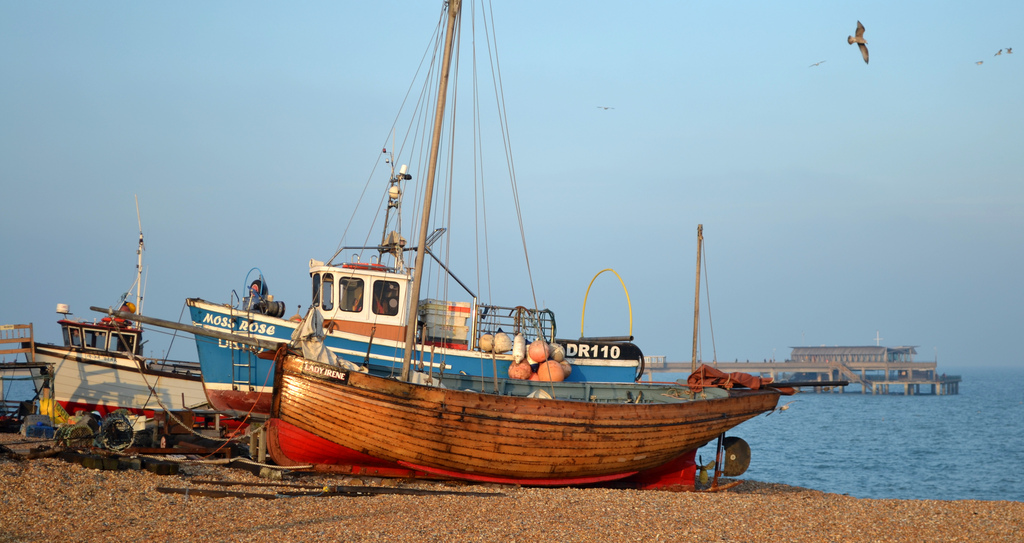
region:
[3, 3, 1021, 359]
blue of daytime sky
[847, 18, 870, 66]
extended wings of flying bird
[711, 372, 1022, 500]
surface of choppy water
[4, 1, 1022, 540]
boats on shore near water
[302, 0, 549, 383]
boat mast with no sail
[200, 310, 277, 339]
white words on blue background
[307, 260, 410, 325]
wheel house of boat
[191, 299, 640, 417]
blue body of boat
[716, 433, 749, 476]
rutter of sail boat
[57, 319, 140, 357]
wheel house of fishing boat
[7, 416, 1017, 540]
rocky beach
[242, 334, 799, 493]
wooden boat sitting on rocky beach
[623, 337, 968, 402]
pier going out into the water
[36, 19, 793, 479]
boats docked on shore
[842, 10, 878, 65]
bird flying high in the sky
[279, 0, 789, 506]
boat with a red bottom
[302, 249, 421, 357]
enclosed control room on a boat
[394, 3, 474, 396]
mast on a sail boat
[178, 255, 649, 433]
blue and white boat on the beach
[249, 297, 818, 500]
Boat docked on the beach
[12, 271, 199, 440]
Boat docked on the beach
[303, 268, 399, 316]
Window on the boat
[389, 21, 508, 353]
oar on the boat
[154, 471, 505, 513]
wood plank on the beach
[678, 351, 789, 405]
brown cloth on the boat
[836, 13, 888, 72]
Bird above the boat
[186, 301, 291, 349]
white letters on the blue boat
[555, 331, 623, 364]
white letters on the boat